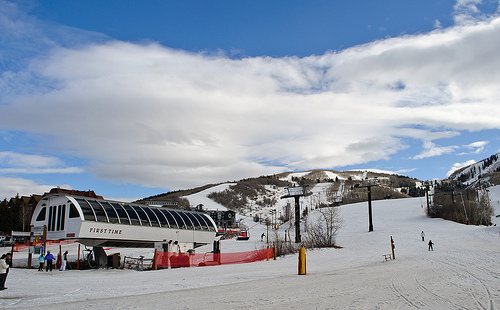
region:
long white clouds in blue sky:
[2, 143, 88, 182]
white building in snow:
[13, 183, 226, 256]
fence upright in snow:
[420, 180, 499, 228]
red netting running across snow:
[152, 243, 282, 271]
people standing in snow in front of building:
[29, 241, 74, 273]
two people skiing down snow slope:
[413, 223, 441, 256]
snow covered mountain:
[135, 159, 431, 232]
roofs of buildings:
[0, 181, 97, 211]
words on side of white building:
[82, 215, 127, 240]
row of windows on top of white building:
[77, 194, 216, 232]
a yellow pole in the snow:
[295, 242, 307, 277]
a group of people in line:
[35, 249, 85, 273]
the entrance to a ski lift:
[26, 190, 227, 242]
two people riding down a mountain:
[412, 226, 441, 254]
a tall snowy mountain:
[211, 165, 413, 227]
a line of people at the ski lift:
[3, 188, 95, 285]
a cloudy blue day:
[7, 0, 295, 170]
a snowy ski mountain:
[203, 160, 423, 242]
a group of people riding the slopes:
[381, 221, 439, 263]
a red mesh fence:
[149, 243, 279, 268]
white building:
[11, 192, 271, 269]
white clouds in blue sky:
[41, 12, 98, 70]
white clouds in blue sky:
[238, 42, 309, 96]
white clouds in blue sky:
[362, 41, 407, 89]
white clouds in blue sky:
[381, 95, 425, 142]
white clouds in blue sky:
[418, 9, 480, 69]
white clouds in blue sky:
[98, 31, 155, 95]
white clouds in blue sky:
[90, 126, 140, 167]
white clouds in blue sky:
[194, 68, 246, 120]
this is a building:
[48, 81, 210, 289]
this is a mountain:
[233, 179, 375, 192]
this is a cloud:
[184, 62, 189, 65]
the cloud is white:
[186, 108, 299, 228]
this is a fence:
[153, 217, 205, 274]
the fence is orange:
[160, 250, 206, 271]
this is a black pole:
[230, 185, 335, 221]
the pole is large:
[260, 182, 315, 305]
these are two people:
[405, 220, 430, 290]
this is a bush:
[430, 156, 483, 221]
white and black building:
[28, 195, 218, 242]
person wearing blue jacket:
[44, 250, 54, 269]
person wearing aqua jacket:
[36, 253, 45, 269]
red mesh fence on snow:
[152, 247, 276, 268]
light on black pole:
[288, 185, 308, 246]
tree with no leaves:
[304, 203, 342, 245]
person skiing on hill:
[428, 239, 434, 249]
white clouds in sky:
[8, 27, 498, 189]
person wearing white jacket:
[0, 253, 10, 286]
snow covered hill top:
[446, 152, 499, 189]